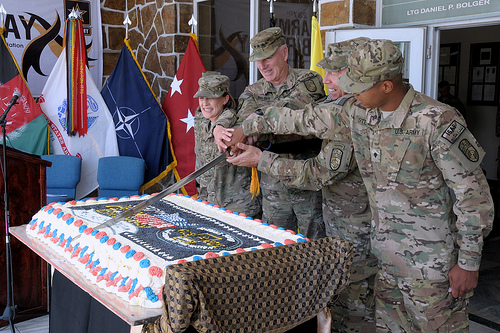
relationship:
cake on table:
[61, 199, 197, 259] [5, 212, 108, 332]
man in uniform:
[334, 73, 399, 110] [332, 107, 449, 190]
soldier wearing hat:
[246, 26, 300, 151] [251, 29, 300, 53]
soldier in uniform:
[246, 26, 300, 151] [332, 107, 449, 190]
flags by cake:
[27, 69, 140, 136] [61, 199, 197, 259]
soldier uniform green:
[246, 26, 300, 151] [343, 123, 432, 211]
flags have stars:
[27, 69, 140, 136] [157, 65, 205, 123]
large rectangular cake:
[76, 188, 280, 312] [61, 199, 197, 259]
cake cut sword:
[61, 199, 197, 259] [102, 134, 258, 203]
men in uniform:
[186, 74, 485, 158] [332, 107, 449, 190]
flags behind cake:
[27, 69, 140, 136] [61, 199, 197, 259]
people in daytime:
[186, 74, 485, 158] [121, 15, 457, 158]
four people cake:
[186, 74, 485, 158] [61, 199, 197, 259]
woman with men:
[183, 69, 239, 151] [186, 74, 485, 158]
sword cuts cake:
[102, 134, 258, 203] [61, 199, 197, 259]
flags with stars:
[27, 69, 140, 136] [157, 65, 205, 123]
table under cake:
[5, 212, 108, 332] [61, 199, 197, 259]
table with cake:
[5, 212, 108, 332] [61, 199, 197, 259]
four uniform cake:
[196, 20, 494, 116] [61, 199, 197, 259]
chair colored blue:
[89, 152, 155, 181] [103, 144, 149, 191]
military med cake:
[121, 203, 227, 256] [61, 199, 197, 259]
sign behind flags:
[11, 6, 70, 58] [27, 69, 140, 136]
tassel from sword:
[237, 158, 274, 197] [102, 134, 258, 203]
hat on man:
[251, 29, 300, 53] [334, 73, 399, 110]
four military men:
[196, 20, 494, 116] [186, 74, 485, 158]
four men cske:
[196, 20, 494, 116] [61, 199, 197, 259]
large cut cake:
[76, 188, 280, 312] [61, 199, 197, 259]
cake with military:
[61, 199, 197, 259] [121, 203, 227, 256]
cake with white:
[61, 199, 197, 259] [50, 203, 125, 268]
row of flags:
[9, 41, 292, 157] [27, 69, 140, 136]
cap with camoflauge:
[329, 41, 396, 82] [329, 121, 404, 243]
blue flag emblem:
[103, 144, 149, 191] [107, 95, 166, 151]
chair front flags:
[89, 152, 155, 181] [27, 69, 140, 136]